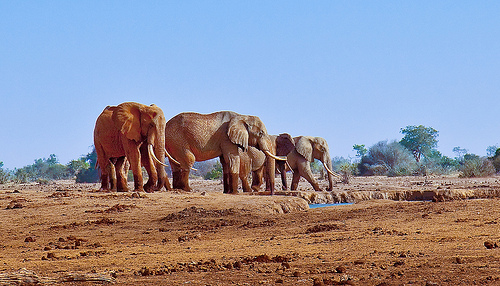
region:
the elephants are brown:
[73, 69, 366, 193]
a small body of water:
[281, 175, 361, 229]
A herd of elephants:
[93, 105, 336, 191]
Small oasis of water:
[305, 200, 356, 205]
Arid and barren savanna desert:
[5, 183, 490, 281]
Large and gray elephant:
[91, 100, 166, 190]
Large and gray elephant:
[165, 110, 270, 191]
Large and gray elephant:
[280, 131, 331, 186]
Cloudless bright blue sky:
[1, 1, 491, 98]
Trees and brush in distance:
[352, 125, 493, 176]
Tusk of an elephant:
[263, 150, 286, 161]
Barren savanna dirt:
[8, 219, 231, 279]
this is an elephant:
[116, 51, 316, 199]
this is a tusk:
[263, 152, 282, 166]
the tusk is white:
[248, 118, 272, 166]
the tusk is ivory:
[129, 136, 251, 176]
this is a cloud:
[157, 66, 185, 83]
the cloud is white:
[161, 31, 222, 88]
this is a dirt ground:
[94, 184, 231, 256]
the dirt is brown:
[190, 209, 242, 264]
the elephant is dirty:
[201, 122, 236, 148]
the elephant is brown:
[183, 119, 191, 140]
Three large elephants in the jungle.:
[71, 68, 353, 206]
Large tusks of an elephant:
[143, 138, 183, 174]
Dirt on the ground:
[51, 198, 203, 272]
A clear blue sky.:
[52, 15, 363, 81]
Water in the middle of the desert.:
[291, 179, 439, 221]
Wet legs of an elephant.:
[172, 164, 246, 196]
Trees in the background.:
[358, 120, 483, 181]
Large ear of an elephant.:
[227, 118, 254, 150]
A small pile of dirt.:
[162, 205, 219, 225]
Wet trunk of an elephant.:
[325, 175, 338, 187]